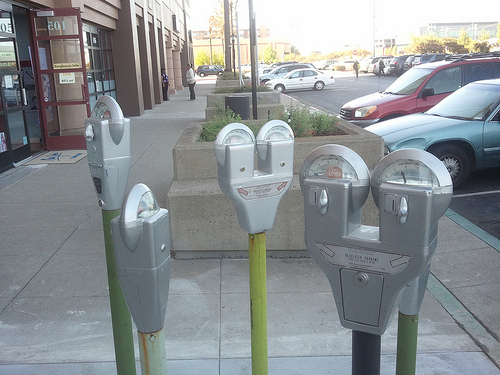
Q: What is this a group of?
A: Parking meters.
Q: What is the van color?
A: Red.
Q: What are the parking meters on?
A: Sidewalk.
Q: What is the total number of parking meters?
A: 7.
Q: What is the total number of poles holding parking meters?
A: 5.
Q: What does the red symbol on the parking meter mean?
A: Time expired.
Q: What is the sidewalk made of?
A: Concrete.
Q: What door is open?
A: Red door.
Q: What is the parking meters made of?
A: Metal.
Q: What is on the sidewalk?
A: Cracks.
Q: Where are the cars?
A: Next to the meters.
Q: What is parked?
A: Cars.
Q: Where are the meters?
A: On the post.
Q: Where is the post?
A: Below the meters.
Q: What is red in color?
A: A car.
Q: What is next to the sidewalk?
A: A store.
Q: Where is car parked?
A: On the road.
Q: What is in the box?
A: Bushes.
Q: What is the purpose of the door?
A: Door to a shop.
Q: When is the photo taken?
A: During the day.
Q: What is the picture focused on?
A: Parking meters.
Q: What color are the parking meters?
A: Silver.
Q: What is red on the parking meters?
A: The expired sign.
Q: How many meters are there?
A: Six.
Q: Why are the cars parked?
A: To visit the business.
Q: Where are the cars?
A: In the parking lot.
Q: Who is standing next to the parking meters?
A: No one.